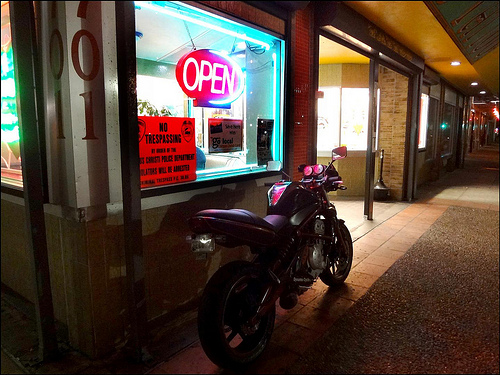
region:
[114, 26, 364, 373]
a motorcycle in front a window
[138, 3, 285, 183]
a sign OPEN hangs from window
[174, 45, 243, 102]
sign OPEN has white letters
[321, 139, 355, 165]
a mirror on front a motorcycle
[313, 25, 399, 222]
door of store are open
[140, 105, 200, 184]
an orange sign on a window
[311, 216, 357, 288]
front wheel of motorcycle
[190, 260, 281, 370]
back wheel of motorcycle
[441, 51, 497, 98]
lights on a ceiling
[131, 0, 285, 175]
lights around the window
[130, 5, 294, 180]
front window of open business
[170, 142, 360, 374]
parked motorcycle in front of business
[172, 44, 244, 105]
open sign in window of business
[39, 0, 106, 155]
address number of business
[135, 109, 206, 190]
red no trespassing sign in corner of window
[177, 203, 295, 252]
driver and passenger seats on motorcycle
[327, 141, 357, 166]
right rear view mirror on motorcycle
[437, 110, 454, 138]
reflection of green light on window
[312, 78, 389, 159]
window with lights on inside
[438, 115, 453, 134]
green light reflecting on building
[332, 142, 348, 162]
mirror on the bike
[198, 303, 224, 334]
black tire on the bike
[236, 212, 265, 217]
black seat on the bike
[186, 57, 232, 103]
red and white open sign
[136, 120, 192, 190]
red and black sign in the window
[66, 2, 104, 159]
brown numbers on the building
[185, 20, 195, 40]
chain hanging on the sign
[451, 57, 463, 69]
white lights on the building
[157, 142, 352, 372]
motorcycle outside building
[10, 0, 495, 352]
building on the left behind motorcycle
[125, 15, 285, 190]
window with neon lights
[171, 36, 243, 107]
neon open sign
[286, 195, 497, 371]
cement with small rocks inside of it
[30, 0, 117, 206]
part of the building number is 701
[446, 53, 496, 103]
lights underneath the sign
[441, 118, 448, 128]
green traffic light reflected in window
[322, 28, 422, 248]
entrance way to store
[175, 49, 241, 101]
red and white neon Open sign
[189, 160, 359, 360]
motorcycle parked outside a business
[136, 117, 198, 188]
a red no trespassing sign on store window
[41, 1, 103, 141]
address number written on corner of business in red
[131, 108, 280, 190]
three posters on store window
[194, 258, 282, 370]
motorcycle has a back wheel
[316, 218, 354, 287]
motorcycle has a front wheel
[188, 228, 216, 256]
backlight of motorcycle is shiny and reflective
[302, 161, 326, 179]
dials on motorcycle dashboard glow red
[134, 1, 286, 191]
blue neon lights bordering store window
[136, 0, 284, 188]
Glass window with Open sign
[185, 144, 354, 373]
Motorcycle has two side mirrors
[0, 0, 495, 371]
Interior view, time and season, unclear.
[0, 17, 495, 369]
Retail venues and interior space shown.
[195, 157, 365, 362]
Parked motorcycle with colorful details.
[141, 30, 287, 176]
No tresspassing and open sign in well-lit retail window.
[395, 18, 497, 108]
High ceiling with recessed lighting.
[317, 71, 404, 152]
Uncovered window with light and surrounding brickwork.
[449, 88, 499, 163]
Distant lights and suggestion of stores.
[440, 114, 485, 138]
Blue lights, reflected on wall.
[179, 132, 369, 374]
motorcycle parked by window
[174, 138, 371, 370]
parked motorcycle is black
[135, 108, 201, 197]
sign hanging in window